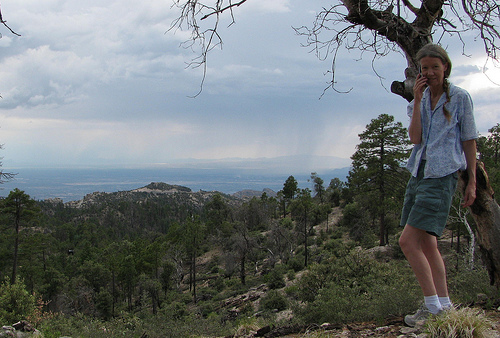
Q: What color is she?
A: White.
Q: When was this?
A: Daytime.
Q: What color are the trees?
A: Green.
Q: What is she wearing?
A: Clothes.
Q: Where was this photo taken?
A: On a mountain.